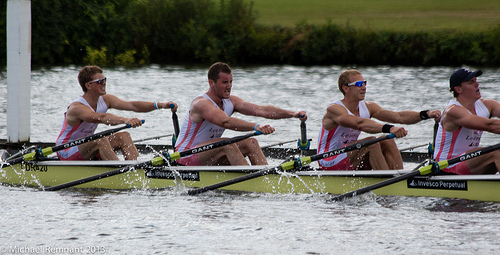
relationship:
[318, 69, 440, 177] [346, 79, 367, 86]
man wears sunglasses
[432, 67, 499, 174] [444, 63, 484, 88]
man wears hat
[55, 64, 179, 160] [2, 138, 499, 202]
man on boat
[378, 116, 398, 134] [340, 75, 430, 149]
sweatbands on wrists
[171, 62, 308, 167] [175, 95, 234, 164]
man wears uniform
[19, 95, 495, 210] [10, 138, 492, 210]
oars on boats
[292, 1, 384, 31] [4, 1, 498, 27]
grass on background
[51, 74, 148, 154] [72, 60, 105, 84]
man has hair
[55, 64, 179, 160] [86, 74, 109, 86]
man wears sunglasses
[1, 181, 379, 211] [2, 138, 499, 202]
wake near boat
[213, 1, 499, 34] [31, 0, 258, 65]
grass behind trees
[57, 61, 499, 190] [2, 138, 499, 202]
team on boat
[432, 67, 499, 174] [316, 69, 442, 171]
man next man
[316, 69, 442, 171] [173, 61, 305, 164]
man next man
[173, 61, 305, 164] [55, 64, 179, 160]
man next man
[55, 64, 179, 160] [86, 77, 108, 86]
man wearing sunglasses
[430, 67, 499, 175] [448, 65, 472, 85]
man wearing hat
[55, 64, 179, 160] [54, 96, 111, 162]
man wearing a uniform